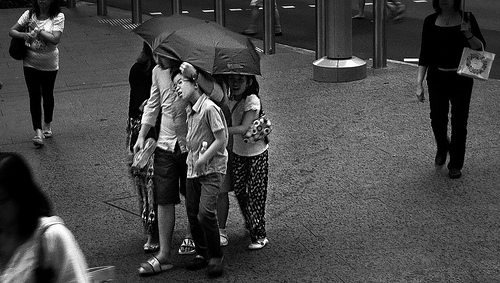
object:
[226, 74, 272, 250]
people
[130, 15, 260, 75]
umbrella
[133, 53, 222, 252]
man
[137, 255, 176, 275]
sandal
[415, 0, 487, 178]
woman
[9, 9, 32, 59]
purse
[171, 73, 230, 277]
boy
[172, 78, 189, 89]
glasses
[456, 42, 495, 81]
paper bag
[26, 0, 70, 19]
hair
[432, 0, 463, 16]
hair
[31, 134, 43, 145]
shoe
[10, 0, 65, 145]
girl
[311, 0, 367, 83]
pillar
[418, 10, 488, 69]
shirt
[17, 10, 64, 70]
shirt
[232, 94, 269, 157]
shirt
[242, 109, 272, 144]
bag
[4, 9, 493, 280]
sidewalk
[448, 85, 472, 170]
leg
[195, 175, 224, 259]
leg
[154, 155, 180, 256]
leg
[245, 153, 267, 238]
leg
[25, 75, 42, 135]
leg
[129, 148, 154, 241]
leg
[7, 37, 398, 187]
floor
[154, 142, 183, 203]
trouser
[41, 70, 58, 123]
trouser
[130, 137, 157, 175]
bottle